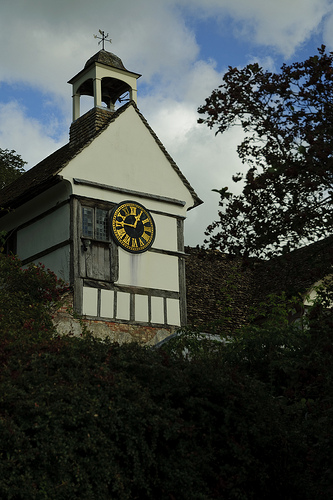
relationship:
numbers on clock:
[113, 204, 153, 251] [104, 200, 156, 257]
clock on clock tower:
[110, 201, 157, 255] [0, 27, 200, 335]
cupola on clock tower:
[66, 26, 142, 142] [0, 27, 200, 335]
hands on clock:
[116, 209, 142, 227] [109, 201, 155, 253]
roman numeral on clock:
[143, 225, 153, 232] [109, 201, 155, 253]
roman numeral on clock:
[140, 231, 150, 240] [109, 201, 155, 253]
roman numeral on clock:
[131, 238, 138, 248] [109, 201, 155, 253]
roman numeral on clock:
[123, 234, 129, 243] [109, 201, 155, 253]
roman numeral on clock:
[129, 205, 136, 215] [109, 201, 155, 253]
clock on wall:
[109, 201, 155, 253] [75, 196, 188, 329]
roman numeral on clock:
[129, 205, 135, 215] [109, 201, 155, 253]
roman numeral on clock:
[141, 215, 150, 224] [109, 201, 155, 253]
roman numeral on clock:
[141, 232, 150, 243] [109, 201, 155, 253]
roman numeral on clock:
[130, 237, 138, 249] [109, 201, 155, 253]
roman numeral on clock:
[116, 228, 125, 236] [109, 201, 155, 253]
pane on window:
[83, 206, 88, 210] [76, 197, 116, 283]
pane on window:
[87, 210, 92, 215] [76, 197, 116, 283]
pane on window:
[96, 215, 100, 220] [76, 197, 116, 283]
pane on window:
[100, 232, 103, 237] [76, 197, 116, 283]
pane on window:
[87, 229, 91, 233] [76, 197, 116, 283]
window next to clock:
[76, 197, 116, 283] [109, 201, 155, 253]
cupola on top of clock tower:
[66, 26, 143, 120] [0, 27, 332, 497]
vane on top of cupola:
[89, 26, 112, 48] [66, 48, 141, 146]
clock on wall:
[110, 201, 157, 255] [55, 99, 200, 328]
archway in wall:
[302, 273, 332, 331] [184, 235, 332, 345]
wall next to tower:
[184, 235, 332, 345] [56, 40, 173, 285]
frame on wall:
[73, 277, 188, 332] [55, 99, 200, 328]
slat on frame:
[95, 287, 102, 314] [73, 277, 188, 332]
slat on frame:
[112, 290, 118, 318] [73, 277, 188, 332]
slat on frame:
[128, 294, 136, 321] [73, 277, 188, 332]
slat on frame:
[147, 296, 152, 322] [73, 277, 188, 332]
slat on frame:
[162, 297, 168, 324] [73, 277, 188, 332]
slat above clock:
[72, 175, 186, 206] [108, 197, 154, 255]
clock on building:
[110, 201, 157, 255] [0, 28, 204, 344]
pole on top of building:
[100, 40, 104, 49] [12, 27, 201, 323]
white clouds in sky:
[2, 1, 331, 245] [0, 0, 332, 259]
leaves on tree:
[194, 60, 328, 339] [196, 43, 332, 305]